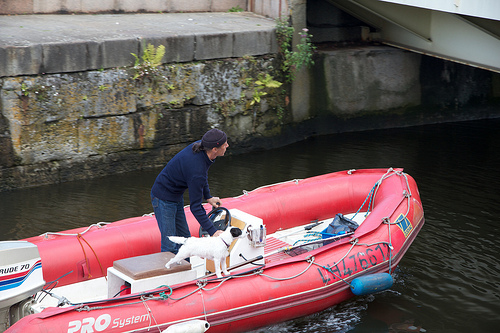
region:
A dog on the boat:
[168, 220, 244, 276]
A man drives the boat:
[133, 97, 238, 259]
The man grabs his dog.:
[187, 177, 224, 244]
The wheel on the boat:
[196, 200, 233, 248]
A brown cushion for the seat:
[107, 246, 189, 284]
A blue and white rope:
[357, 181, 381, 218]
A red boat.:
[20, 156, 427, 331]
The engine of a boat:
[0, 233, 48, 331]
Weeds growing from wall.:
[116, 45, 175, 73]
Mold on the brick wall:
[21, 73, 243, 136]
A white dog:
[167, 225, 240, 275]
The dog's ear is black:
[229, 224, 241, 239]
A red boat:
[0, 167, 434, 326]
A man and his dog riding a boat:
[0, 135, 427, 323]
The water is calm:
[427, 130, 485, 210]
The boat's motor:
[0, 231, 53, 321]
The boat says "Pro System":
[67, 310, 154, 329]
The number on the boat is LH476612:
[315, 242, 402, 283]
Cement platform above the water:
[2, 12, 282, 58]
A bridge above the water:
[370, 0, 497, 80]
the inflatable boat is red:
[321, 147, 428, 323]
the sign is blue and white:
[387, 212, 435, 243]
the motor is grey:
[3, 222, 55, 315]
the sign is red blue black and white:
[1, 257, 62, 304]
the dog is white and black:
[170, 222, 251, 279]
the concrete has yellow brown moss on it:
[8, 72, 143, 134]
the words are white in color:
[65, 311, 157, 331]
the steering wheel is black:
[191, 198, 243, 249]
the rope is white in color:
[42, 225, 109, 243]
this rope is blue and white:
[350, 182, 389, 220]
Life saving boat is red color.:
[31, 183, 425, 315]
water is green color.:
[422, 278, 493, 319]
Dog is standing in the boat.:
[164, 213, 257, 274]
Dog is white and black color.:
[168, 225, 248, 276]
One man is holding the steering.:
[133, 123, 234, 260]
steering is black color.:
[193, 203, 237, 246]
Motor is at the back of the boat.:
[0, 241, 50, 301]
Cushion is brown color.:
[107, 247, 190, 282]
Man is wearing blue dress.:
[143, 150, 211, 247]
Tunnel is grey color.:
[19, 32, 496, 132]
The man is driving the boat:
[128, 113, 275, 268]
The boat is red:
[21, 142, 428, 315]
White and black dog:
[146, 221, 262, 275]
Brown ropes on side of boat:
[185, 181, 419, 310]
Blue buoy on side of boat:
[326, 253, 403, 295]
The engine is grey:
[4, 229, 65, 321]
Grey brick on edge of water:
[1, 11, 321, 181]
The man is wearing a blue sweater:
[141, 126, 248, 237]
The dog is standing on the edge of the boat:
[161, 215, 249, 286]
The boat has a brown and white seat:
[104, 248, 204, 290]